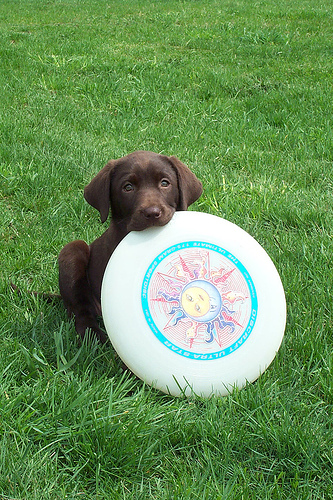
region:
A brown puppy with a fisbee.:
[50, 147, 293, 410]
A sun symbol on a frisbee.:
[138, 239, 260, 362]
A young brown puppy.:
[55, 144, 200, 341]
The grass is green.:
[18, 365, 121, 471]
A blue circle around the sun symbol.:
[138, 237, 263, 367]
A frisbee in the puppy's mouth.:
[85, 151, 286, 394]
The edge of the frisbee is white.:
[97, 229, 155, 382]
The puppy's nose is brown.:
[142, 203, 166, 223]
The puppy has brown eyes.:
[113, 169, 176, 196]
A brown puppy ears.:
[72, 157, 122, 224]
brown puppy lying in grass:
[5, 141, 203, 376]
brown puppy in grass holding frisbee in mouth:
[7, 146, 292, 400]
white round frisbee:
[97, 208, 292, 400]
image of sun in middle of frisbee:
[147, 244, 253, 350]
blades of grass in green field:
[21, 382, 324, 499]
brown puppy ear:
[67, 158, 120, 230]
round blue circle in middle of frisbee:
[140, 238, 259, 362]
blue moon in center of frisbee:
[178, 278, 221, 318]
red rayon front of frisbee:
[173, 251, 197, 280]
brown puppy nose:
[141, 203, 160, 221]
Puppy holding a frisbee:
[47, 121, 277, 372]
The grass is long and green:
[72, 403, 130, 461]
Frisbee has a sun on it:
[141, 238, 255, 354]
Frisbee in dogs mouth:
[89, 161, 200, 232]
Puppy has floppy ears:
[76, 155, 126, 222]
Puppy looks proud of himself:
[89, 143, 243, 236]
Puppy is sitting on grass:
[9, 221, 120, 349]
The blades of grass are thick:
[30, 367, 130, 476]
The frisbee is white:
[63, 197, 300, 386]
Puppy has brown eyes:
[120, 178, 135, 195]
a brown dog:
[85, 143, 199, 228]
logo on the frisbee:
[152, 266, 243, 338]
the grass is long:
[73, 387, 160, 454]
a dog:
[66, 148, 201, 211]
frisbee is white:
[108, 267, 138, 305]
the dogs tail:
[5, 278, 56, 306]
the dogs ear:
[82, 178, 117, 222]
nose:
[141, 204, 167, 218]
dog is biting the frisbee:
[130, 215, 178, 234]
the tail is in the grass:
[11, 278, 53, 305]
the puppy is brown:
[21, 95, 182, 302]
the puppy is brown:
[69, 153, 232, 341]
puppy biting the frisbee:
[88, 136, 244, 373]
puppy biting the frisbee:
[44, 146, 285, 434]